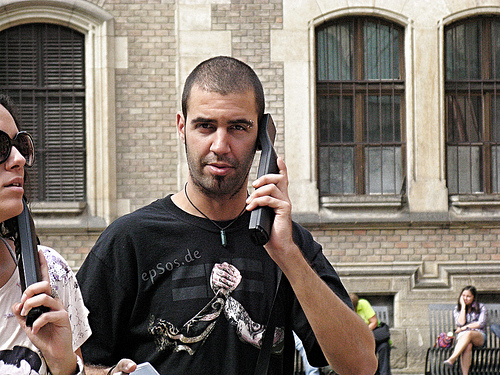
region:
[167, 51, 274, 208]
a man with short hair.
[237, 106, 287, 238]
a large black phone.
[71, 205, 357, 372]
a black t shirt.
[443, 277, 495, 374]
A woman sitting on a bench.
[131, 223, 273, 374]
a picture on a black t shirt.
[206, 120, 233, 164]
a man with a shiny nose.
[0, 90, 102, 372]
A woman with dark sun glasses.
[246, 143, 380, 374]
A right human hand.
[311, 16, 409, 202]
a very large window on a building.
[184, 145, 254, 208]
patchy facial hair.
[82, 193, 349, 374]
a black short sleeve shirt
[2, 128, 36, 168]
a pair of sunglasses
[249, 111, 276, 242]
a large black communication device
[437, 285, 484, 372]
a woman sitting down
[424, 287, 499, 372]
a lady on a bench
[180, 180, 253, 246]
a black necklace with pendant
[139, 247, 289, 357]
arm wrestling decal on shirt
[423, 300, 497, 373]
a metal framed bench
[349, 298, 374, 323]
a yellow short sleeve shirt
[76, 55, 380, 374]
a man on a phone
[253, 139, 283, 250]
a phone the man is holding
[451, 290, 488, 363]
lady on the bench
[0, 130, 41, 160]
women wearing sunglasses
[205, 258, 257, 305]
hands on the shirt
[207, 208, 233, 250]
man is wearing a necklace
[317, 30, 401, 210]
windows on the building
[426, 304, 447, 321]
the bench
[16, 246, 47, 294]
a black phone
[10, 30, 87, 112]
a window on the building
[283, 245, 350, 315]
the mans arm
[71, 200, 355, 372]
Man is wearing a shirt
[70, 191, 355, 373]
Man is wearing a black shirt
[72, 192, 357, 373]
Man is wearing a t-shirt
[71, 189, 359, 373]
Man is wearing a black t-shirt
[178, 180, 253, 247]
Man is wearing a necklace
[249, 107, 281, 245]
Man is on the phone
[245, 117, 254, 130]
Man has a piercing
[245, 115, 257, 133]
Man has an eyebrow piercing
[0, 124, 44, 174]
Woman is wearing sunglasses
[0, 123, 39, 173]
Woman is wearing black sunglasses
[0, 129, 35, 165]
the sunglasses on the woman's face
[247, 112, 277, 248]
the object up to the man's head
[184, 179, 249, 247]
the necklace on the man's neck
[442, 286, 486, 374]
the woman sitting on the bench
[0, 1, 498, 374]
the large building in the back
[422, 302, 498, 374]
the bench under the woman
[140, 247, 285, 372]
the design on the man's shirt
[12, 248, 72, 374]
the woman's left hand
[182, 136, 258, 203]
the short facial hair on the man's head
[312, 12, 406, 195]
the window on the building